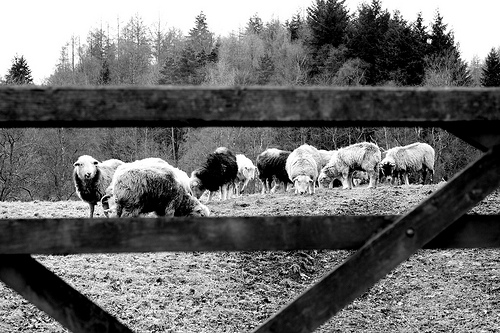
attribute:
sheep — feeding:
[72, 139, 443, 214]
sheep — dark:
[188, 147, 238, 201]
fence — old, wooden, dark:
[3, 71, 499, 331]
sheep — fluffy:
[105, 154, 209, 218]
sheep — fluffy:
[73, 151, 125, 209]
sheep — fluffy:
[380, 137, 437, 179]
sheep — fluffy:
[316, 140, 386, 192]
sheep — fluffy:
[287, 141, 319, 197]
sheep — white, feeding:
[281, 143, 326, 198]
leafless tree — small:
[2, 127, 33, 201]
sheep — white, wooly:
[282, 141, 327, 196]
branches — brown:
[2, 129, 68, 207]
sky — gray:
[0, 2, 497, 86]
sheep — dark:
[194, 150, 236, 197]